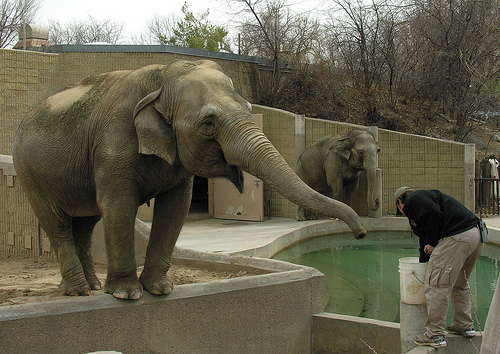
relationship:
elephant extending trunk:
[9, 57, 368, 301] [213, 112, 367, 240]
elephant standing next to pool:
[9, 57, 368, 301] [269, 227, 485, 331]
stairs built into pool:
[284, 253, 400, 321] [269, 227, 485, 331]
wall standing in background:
[250, 101, 476, 218] [1, 1, 484, 225]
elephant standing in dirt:
[9, 57, 368, 301] [0, 250, 264, 304]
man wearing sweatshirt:
[387, 177, 484, 350] [400, 185, 483, 264]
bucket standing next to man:
[395, 256, 429, 306] [387, 177, 484, 350]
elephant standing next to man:
[9, 57, 368, 301] [387, 177, 484, 350]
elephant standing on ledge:
[9, 57, 368, 301] [1, 248, 323, 352]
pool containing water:
[265, 215, 484, 352] [269, 228, 485, 332]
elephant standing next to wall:
[290, 125, 380, 220] [250, 101, 476, 218]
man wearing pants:
[387, 177, 484, 350] [420, 226, 484, 337]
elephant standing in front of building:
[9, 57, 368, 301] [0, 20, 476, 220]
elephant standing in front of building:
[290, 125, 380, 220] [0, 20, 476, 220]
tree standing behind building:
[1, 0, 42, 50] [0, 20, 476, 220]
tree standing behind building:
[43, 15, 126, 45] [0, 20, 476, 220]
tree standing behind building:
[156, 1, 229, 51] [0, 20, 476, 220]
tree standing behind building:
[211, 0, 326, 112] [0, 20, 476, 220]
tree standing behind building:
[322, 1, 408, 131] [0, 20, 476, 220]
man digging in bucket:
[387, 177, 484, 350] [397, 253, 431, 304]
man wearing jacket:
[392, 177, 484, 350] [401, 189, 481, 258]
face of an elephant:
[165, 79, 275, 197] [17, 58, 327, 289]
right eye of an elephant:
[202, 113, 218, 126] [21, 52, 381, 312]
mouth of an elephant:
[225, 161, 252, 193] [9, 57, 368, 301]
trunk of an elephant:
[241, 144, 395, 253] [6, 35, 368, 349]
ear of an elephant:
[116, 93, 178, 158] [9, 57, 368, 301]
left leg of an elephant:
[143, 182, 198, 292] [15, 41, 405, 305]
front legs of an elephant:
[103, 178, 147, 299] [9, 49, 403, 344]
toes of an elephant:
[99, 276, 154, 314] [21, 52, 381, 312]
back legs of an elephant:
[36, 204, 97, 296] [21, 52, 381, 312]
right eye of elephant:
[196, 107, 218, 137] [9, 49, 403, 344]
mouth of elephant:
[211, 142, 259, 198] [26, 30, 378, 301]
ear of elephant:
[131, 93, 177, 165] [9, 57, 368, 301]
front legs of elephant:
[83, 178, 184, 299] [21, 52, 381, 312]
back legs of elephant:
[31, 204, 101, 311] [9, 49, 403, 344]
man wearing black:
[392, 177, 484, 350] [398, 190, 480, 250]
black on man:
[398, 190, 480, 250] [376, 177, 458, 251]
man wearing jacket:
[392, 177, 484, 350] [403, 193, 479, 251]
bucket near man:
[395, 256, 423, 302] [384, 175, 449, 253]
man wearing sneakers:
[392, 177, 484, 350] [418, 327, 461, 351]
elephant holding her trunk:
[9, 57, 368, 301] [204, 134, 371, 261]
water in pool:
[305, 242, 395, 308] [283, 216, 496, 333]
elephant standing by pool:
[290, 125, 380, 220] [281, 204, 496, 324]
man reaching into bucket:
[387, 177, 484, 350] [389, 254, 433, 308]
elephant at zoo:
[9, 57, 368, 301] [6, 20, 498, 352]